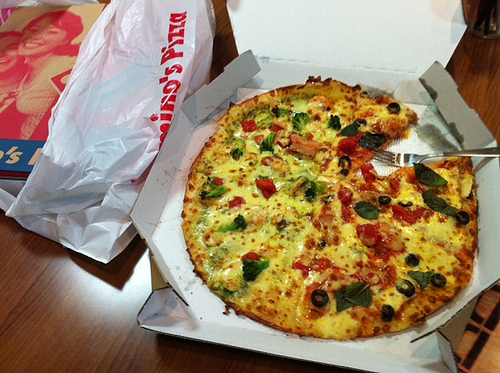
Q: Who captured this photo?
A: A photographer.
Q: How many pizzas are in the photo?
A: One.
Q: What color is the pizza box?
A: White.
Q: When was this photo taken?
A: In the daytime.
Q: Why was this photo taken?
A: To show pizza.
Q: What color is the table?
A: Brown.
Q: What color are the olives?
A: Black.